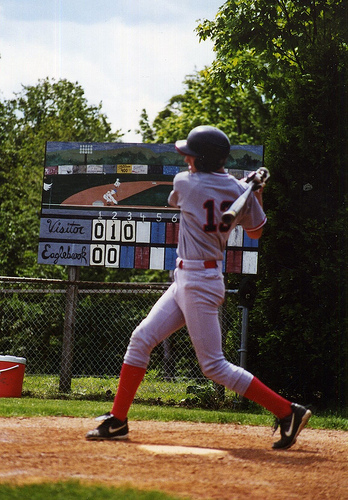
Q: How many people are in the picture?
A: One.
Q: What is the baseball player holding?
A: A bat.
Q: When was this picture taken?
A: During the day.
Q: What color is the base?
A: White.